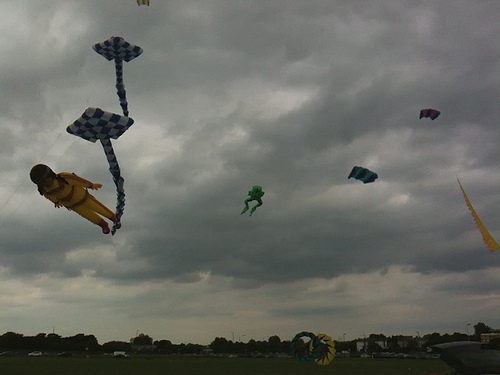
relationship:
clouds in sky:
[0, 1, 497, 345] [0, 2, 499, 322]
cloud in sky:
[125, 68, 497, 286] [0, 2, 499, 322]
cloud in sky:
[91, 3, 496, 81] [0, 2, 499, 322]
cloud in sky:
[1, 191, 112, 282] [0, 2, 499, 322]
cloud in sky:
[2, 1, 100, 128] [0, 2, 499, 322]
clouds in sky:
[154, 52, 328, 157] [0, 2, 499, 322]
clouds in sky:
[111, 112, 479, 297] [0, 2, 499, 322]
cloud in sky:
[262, 289, 375, 316] [0, 2, 499, 322]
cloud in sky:
[5, 219, 120, 289] [0, 2, 499, 322]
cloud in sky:
[334, 10, 475, 94] [0, 2, 499, 322]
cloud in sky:
[204, 28, 365, 163] [0, 2, 499, 322]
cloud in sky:
[415, 183, 497, 271] [0, 2, 499, 322]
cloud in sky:
[239, 70, 330, 127] [0, 2, 499, 322]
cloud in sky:
[122, 115, 193, 166] [0, 2, 499, 322]